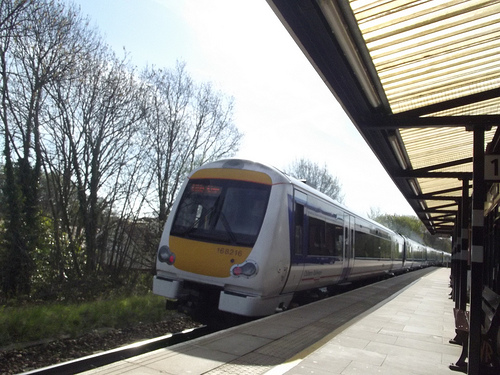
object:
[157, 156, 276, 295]
front is yellow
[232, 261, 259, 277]
train has headlights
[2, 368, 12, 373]
gravel by tracks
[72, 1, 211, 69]
sky is blue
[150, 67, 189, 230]
tree is brown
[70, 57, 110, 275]
tree is brown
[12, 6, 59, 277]
tree is brown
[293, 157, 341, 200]
tree is brown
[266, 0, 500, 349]
building has roof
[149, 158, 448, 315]
train is white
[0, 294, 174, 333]
grass is green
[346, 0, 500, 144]
roof is brown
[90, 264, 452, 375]
tiles are brick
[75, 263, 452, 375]
platform by train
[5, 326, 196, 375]
track is metal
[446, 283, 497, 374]
bench is brown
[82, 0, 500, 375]
depot for train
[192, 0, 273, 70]
cloud is white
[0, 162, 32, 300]
tree is green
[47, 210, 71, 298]
tree is green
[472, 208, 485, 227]
marking is white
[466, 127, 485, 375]
post is metal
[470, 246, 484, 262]
marking is white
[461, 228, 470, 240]
marking is white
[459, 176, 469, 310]
post is metal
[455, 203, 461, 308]
post is metal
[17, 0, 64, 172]
tree is bare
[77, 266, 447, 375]
walkway beside train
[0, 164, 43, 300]
plants are green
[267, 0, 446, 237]
roof has dark edge